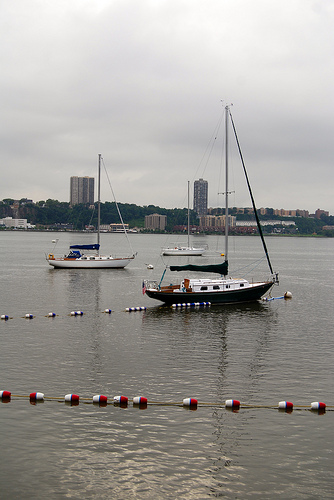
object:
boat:
[143, 100, 279, 305]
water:
[0, 230, 334, 500]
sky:
[0, 0, 334, 204]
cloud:
[102, 17, 246, 97]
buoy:
[182, 397, 197, 406]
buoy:
[49, 312, 56, 318]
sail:
[170, 261, 228, 276]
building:
[70, 176, 94, 204]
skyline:
[4, 197, 333, 220]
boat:
[45, 152, 139, 269]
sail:
[70, 244, 100, 251]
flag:
[142, 279, 147, 296]